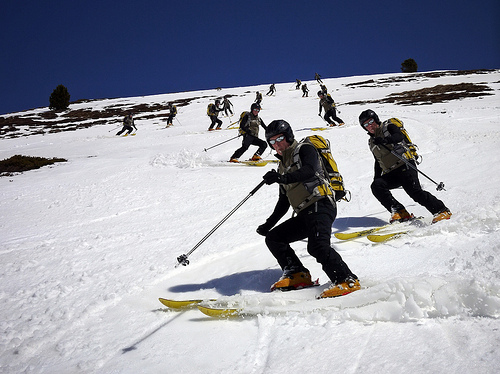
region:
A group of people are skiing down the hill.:
[2, 2, 494, 372]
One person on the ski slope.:
[155, 111, 375, 331]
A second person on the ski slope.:
[331, 101, 456, 241]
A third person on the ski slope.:
[225, 95, 270, 165]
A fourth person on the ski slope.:
[310, 85, 345, 125]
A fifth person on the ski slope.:
[200, 95, 225, 130]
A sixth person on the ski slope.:
[111, 105, 136, 135]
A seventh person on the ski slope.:
[160, 96, 180, 126]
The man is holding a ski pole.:
[173, 168, 278, 272]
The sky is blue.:
[0, 2, 497, 50]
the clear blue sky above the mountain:
[2, 2, 499, 116]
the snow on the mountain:
[0, 68, 498, 371]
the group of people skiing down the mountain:
[106, 69, 451, 316]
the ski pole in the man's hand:
[173, 167, 279, 267]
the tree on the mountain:
[48, 83, 70, 112]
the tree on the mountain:
[399, 58, 417, 71]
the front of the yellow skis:
[157, 296, 247, 318]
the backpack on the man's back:
[295, 133, 350, 205]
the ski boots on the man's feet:
[271, 268, 361, 298]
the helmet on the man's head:
[265, 119, 294, 149]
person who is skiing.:
[147, 94, 379, 316]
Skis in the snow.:
[158, 261, 369, 343]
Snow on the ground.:
[186, 232, 416, 372]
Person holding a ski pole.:
[152, 101, 467, 322]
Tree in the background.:
[41, 73, 130, 160]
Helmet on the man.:
[222, 97, 385, 217]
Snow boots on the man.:
[221, 215, 401, 360]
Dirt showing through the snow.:
[33, 85, 218, 199]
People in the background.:
[176, 66, 370, 148]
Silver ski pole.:
[140, 150, 372, 302]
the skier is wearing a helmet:
[263, 118, 290, 145]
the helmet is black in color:
[265, 118, 294, 147]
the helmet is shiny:
[264, 118, 296, 152]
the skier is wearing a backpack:
[300, 135, 347, 200]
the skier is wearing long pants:
[265, 205, 357, 281]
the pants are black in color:
[266, 213, 352, 282]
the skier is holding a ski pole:
[177, 172, 286, 269]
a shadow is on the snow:
[169, 260, 310, 296]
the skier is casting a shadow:
[173, 125, 369, 298]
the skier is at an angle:
[259, 116, 362, 292]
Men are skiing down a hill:
[90, 95, 467, 335]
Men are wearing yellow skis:
[149, 296, 478, 315]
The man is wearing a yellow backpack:
[296, 129, 378, 251]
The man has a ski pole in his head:
[135, 196, 316, 276]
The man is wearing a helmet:
[256, 118, 329, 174]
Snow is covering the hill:
[29, 133, 295, 367]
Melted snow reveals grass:
[12, 141, 117, 213]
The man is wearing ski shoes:
[253, 250, 410, 316]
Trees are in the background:
[398, 43, 445, 83]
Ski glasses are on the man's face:
[242, 120, 362, 184]